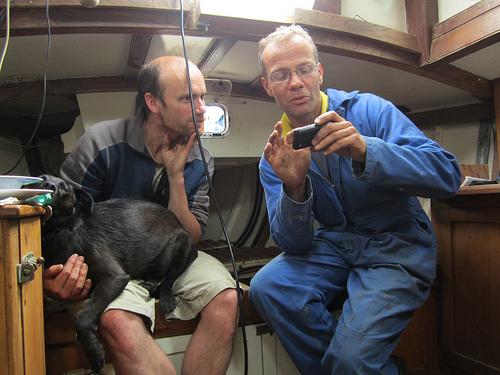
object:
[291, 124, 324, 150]
cellphone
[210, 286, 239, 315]
lap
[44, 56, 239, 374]
man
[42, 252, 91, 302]
hand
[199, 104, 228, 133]
window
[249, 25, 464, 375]
man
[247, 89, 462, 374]
overalls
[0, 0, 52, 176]
wires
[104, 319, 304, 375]
cabinets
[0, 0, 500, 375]
storage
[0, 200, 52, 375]
cabinet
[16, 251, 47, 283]
lock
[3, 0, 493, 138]
frame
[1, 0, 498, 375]
boat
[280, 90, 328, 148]
collar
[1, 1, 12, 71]
cord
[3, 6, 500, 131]
ceiling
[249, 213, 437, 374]
trouser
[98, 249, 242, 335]
shorts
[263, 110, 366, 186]
both hands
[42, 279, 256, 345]
bench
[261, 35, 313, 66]
wide forehead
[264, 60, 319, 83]
eyeglasses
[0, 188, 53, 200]
dishes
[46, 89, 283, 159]
wall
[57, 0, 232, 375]
left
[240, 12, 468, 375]
right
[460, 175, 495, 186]
papers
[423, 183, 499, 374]
cabinet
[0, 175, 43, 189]
cup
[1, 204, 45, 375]
cupboard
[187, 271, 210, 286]
cream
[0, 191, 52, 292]
colors